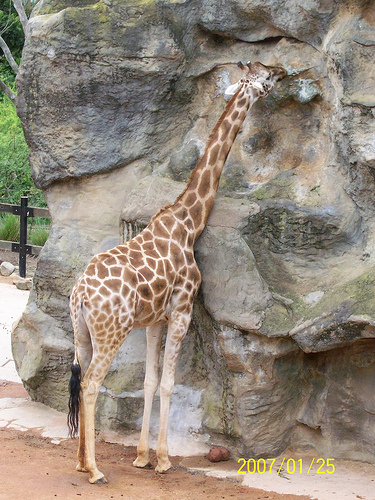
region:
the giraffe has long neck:
[163, 52, 302, 244]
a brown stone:
[199, 437, 246, 470]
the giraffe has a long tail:
[49, 264, 126, 455]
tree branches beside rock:
[0, 0, 136, 127]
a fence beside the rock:
[0, 195, 83, 281]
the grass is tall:
[0, 95, 46, 234]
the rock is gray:
[15, 4, 371, 260]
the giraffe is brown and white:
[39, 56, 309, 358]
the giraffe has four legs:
[40, 286, 243, 481]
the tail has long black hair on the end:
[50, 349, 98, 439]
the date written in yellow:
[223, 443, 350, 482]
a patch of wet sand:
[3, 407, 300, 498]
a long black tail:
[49, 352, 87, 435]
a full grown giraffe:
[25, 35, 279, 464]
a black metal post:
[15, 194, 44, 280]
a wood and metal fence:
[0, 194, 61, 273]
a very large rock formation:
[18, 7, 348, 472]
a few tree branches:
[0, 7, 59, 112]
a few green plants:
[0, 70, 53, 215]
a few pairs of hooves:
[127, 456, 181, 478]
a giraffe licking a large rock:
[16, 3, 369, 397]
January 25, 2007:
[223, 443, 348, 497]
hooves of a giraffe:
[52, 456, 201, 494]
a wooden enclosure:
[0, 184, 36, 277]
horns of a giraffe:
[222, 50, 272, 77]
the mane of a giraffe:
[152, 71, 257, 239]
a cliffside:
[21, 35, 333, 312]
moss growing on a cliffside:
[261, 282, 353, 345]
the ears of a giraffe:
[220, 75, 284, 104]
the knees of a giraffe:
[137, 368, 208, 403]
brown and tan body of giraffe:
[90, 249, 176, 474]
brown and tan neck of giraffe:
[199, 105, 220, 263]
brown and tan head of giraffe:
[229, 60, 324, 124]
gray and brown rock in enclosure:
[29, 23, 159, 154]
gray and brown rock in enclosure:
[216, 279, 362, 446]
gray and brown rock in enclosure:
[58, 184, 130, 236]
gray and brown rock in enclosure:
[9, 300, 63, 402]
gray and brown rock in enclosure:
[260, 125, 369, 251]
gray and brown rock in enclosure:
[69, 9, 342, 52]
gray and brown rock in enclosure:
[97, 23, 203, 148]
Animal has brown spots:
[13, 56, 316, 488]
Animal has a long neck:
[154, 59, 295, 245]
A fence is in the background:
[1, 180, 59, 296]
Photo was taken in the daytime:
[4, 0, 369, 488]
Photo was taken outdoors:
[4, 3, 371, 490]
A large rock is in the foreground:
[0, 0, 373, 453]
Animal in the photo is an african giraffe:
[60, 48, 306, 487]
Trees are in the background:
[0, 0, 18, 185]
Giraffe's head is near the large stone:
[214, 49, 313, 118]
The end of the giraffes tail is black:
[56, 354, 91, 444]